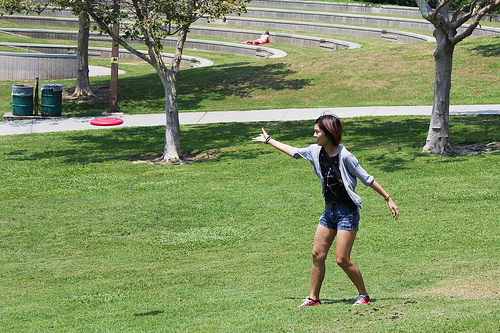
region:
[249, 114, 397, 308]
a woman in a park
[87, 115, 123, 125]
a red frisbee in the air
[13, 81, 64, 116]
two green garbage can in a park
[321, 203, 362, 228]
woman wearing blue jeans shorts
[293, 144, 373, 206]
woman wearing a gray cardigan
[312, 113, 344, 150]
woman with short hair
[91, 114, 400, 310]
a woman throwing a frisbee in a park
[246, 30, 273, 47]
a person sunbathing on a towel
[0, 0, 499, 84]
stones benches in an arena in a park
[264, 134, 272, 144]
woman wearing a bracelet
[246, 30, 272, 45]
person sunbathing in the background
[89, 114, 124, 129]
red Frisbee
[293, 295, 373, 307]
red Converse brand low top shoes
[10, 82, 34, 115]
green painted trash barrel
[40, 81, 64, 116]
green painted trash barrel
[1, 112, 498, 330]
open grassy area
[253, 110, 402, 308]
young woman playing with a Frisbee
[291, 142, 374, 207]
light grey shirt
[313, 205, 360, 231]
distressed blue jean shorts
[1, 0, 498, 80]
round amphitheater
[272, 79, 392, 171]
the head of a woman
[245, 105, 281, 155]
the hand of a woman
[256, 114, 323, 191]
the arm of a woman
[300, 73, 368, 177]
the hair of a woman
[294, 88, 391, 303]
the body of a woman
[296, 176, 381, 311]
the legs of a woman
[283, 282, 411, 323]
the feet of a woman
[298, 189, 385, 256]
a woman wearing shorts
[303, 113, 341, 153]
the face of a woman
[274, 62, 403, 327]
a woman standing on grass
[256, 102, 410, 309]
this is a lady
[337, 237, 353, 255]
the lady is light skinned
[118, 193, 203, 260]
this is a grass area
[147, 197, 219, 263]
the grass is green in color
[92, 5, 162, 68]
this is a tree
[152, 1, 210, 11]
the leaves are green in color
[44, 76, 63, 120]
this is a drum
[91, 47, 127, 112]
this is a pole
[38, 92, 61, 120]
the drum is green in color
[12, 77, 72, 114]
the drums are two in number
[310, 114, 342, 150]
the head of a woman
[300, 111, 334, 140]
the eye of a woman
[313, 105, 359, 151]
the hair of a woman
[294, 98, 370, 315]
a woman standing on grass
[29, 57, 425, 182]
a woman throwing a frisbee